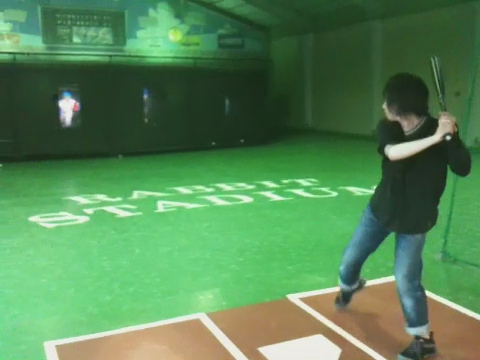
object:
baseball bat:
[428, 54, 452, 141]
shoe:
[334, 278, 367, 309]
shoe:
[394, 331, 436, 359]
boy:
[333, 72, 471, 360]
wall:
[0, 0, 270, 159]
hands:
[435, 121, 456, 140]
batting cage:
[440, 43, 480, 271]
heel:
[356, 278, 367, 287]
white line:
[194, 310, 245, 360]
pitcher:
[58, 91, 81, 128]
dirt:
[296, 276, 480, 357]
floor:
[3, 157, 473, 323]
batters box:
[285, 274, 480, 360]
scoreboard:
[38, 1, 129, 47]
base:
[257, 332, 344, 360]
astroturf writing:
[27, 177, 377, 229]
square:
[284, 276, 479, 360]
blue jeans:
[336, 199, 431, 337]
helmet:
[62, 90, 73, 99]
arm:
[375, 121, 441, 163]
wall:
[271, 32, 479, 146]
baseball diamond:
[41, 275, 479, 360]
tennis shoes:
[395, 331, 437, 359]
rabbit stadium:
[25, 178, 378, 230]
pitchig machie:
[55, 88, 83, 129]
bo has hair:
[381, 73, 430, 121]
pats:
[341, 213, 446, 326]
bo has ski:
[379, 122, 458, 164]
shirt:
[369, 114, 471, 234]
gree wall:
[279, 33, 472, 158]